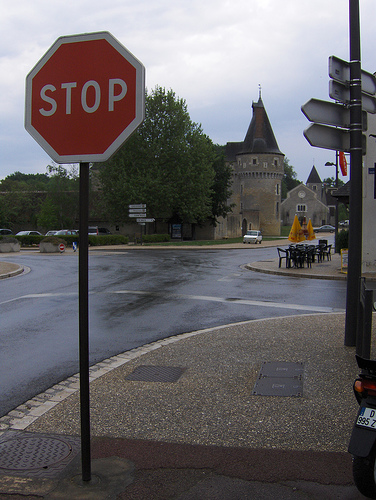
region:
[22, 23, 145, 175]
stop sign on pole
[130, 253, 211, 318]
wet pavement in intersection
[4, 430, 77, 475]
manhole cover on sidewalk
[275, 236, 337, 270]
chairs on corner sidewalk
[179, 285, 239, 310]
white line in road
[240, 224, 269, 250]
car parked on sidewalk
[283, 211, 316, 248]
closed yellow umbrellas on sidewalk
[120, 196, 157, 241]
street signs on corner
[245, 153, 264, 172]
window on building tower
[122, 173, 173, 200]
tree behind street signs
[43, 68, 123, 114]
white writing on sign.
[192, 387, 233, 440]
gravel on the sidewalk.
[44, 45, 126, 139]
red traffic sign on pole.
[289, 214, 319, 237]
yellow umbrellas on sidewalk.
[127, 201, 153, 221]
street signs to direct traffic.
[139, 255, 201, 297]
condensation on the road.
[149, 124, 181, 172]
green leaves on the trees.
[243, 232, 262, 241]
white vehicle parked on sidewalk.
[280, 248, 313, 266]
chairs surrounding the table.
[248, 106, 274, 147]
conical top of the building.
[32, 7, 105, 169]
A stop sign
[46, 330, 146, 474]
A street corner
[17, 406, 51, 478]
A manhole cover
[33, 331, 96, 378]
A intersection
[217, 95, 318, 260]
A castle on the corner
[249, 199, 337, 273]
A patio dining area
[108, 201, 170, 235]
Street signs on the corner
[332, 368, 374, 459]
A motorcycle along the road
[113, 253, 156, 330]
An asphalt road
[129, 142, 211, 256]
Trees on the corner of the street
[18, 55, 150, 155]
Stop sign is red and white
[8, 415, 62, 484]
Man hole cover next to sign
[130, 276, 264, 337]
White line in street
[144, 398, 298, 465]
Packed down stones as sidewalk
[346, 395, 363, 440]
Small license plate on bike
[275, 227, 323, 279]
Tables and chairs on the corner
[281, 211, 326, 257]
Large yellow umbrellas at tables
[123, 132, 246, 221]
Large tree in front of building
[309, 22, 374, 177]
Many street signs connected to pole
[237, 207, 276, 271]
White car parked across the street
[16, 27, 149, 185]
red and white stop sign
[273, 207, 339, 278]
table and chairs on sidewalk patio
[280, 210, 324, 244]
yellow umbrellas to cover tables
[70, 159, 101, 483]
black pole attached to stop sign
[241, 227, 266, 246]
white car parked on sidewalk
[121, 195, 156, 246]
long white signs pointing in different directions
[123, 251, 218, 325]
shiny street wet from rain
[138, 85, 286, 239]
brick building with tower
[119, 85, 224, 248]
large tall green leafy tree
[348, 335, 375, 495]
small motorcycle parked on sidewalk